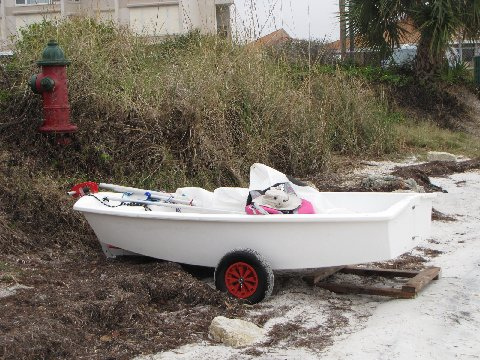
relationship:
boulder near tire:
[203, 308, 276, 349] [218, 245, 277, 312]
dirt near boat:
[7, 232, 200, 347] [68, 190, 430, 307]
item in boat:
[232, 159, 322, 221] [84, 164, 419, 307]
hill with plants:
[6, 37, 410, 190] [349, 65, 405, 107]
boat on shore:
[66, 183, 443, 304] [3, 170, 478, 357]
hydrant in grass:
[27, 41, 81, 137] [15, 16, 370, 181]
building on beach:
[4, 4, 239, 58] [281, 35, 478, 197]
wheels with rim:
[209, 246, 273, 307] [220, 262, 260, 295]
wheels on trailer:
[209, 246, 273, 307] [68, 174, 441, 291]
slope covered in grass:
[7, 39, 466, 197] [1, 21, 419, 206]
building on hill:
[71, 4, 162, 36] [6, 37, 410, 190]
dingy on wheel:
[67, 180, 437, 305] [214, 248, 273, 304]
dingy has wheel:
[61, 166, 449, 307] [210, 247, 275, 307]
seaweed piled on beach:
[260, 100, 345, 141] [2, 132, 478, 358]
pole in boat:
[96, 180, 208, 206] [64, 159, 434, 306]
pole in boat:
[103, 193, 208, 213] [64, 159, 434, 306]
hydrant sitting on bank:
[27, 41, 81, 137] [3, 61, 478, 234]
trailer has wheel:
[68, 174, 442, 309] [213, 245, 276, 305]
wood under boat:
[306, 244, 444, 315] [60, 137, 431, 309]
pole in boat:
[96, 180, 194, 198] [69, 183, 433, 271]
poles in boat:
[101, 196, 204, 211] [69, 183, 433, 271]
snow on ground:
[138, 163, 478, 358] [3, 117, 478, 358]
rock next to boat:
[208, 314, 263, 349] [65, 180, 435, 297]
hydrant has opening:
[28, 30, 78, 134] [26, 75, 37, 95]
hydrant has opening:
[28, 30, 78, 134] [38, 74, 53, 93]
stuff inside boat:
[244, 198, 313, 217] [76, 170, 435, 308]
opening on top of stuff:
[38, 74, 53, 93] [247, 194, 317, 214]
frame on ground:
[299, 260, 440, 299] [1, 154, 478, 357]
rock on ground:
[208, 314, 263, 349] [3, 117, 478, 358]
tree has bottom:
[334, 0, 479, 102] [376, 67, 478, 133]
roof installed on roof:
[246, 29, 289, 53] [247, 28, 295, 57]